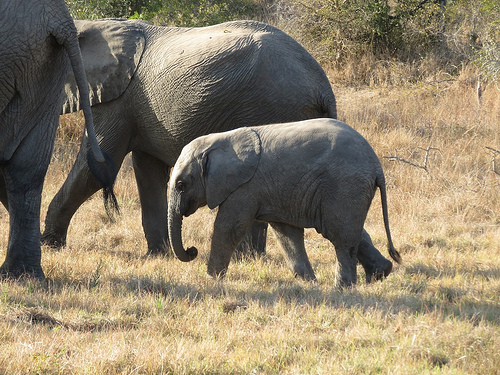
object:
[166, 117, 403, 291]
baby elephant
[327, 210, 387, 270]
legs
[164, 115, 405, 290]
elephant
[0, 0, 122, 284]
parent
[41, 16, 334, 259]
parent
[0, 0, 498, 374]
grass